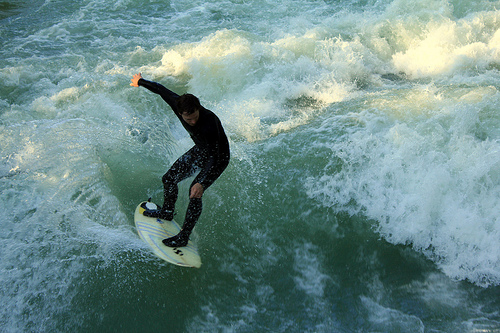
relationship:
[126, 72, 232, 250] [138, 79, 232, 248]
man has wetsuit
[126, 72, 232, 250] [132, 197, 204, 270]
man on surfboard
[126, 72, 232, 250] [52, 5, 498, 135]
man on wave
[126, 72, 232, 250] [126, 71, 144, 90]
man has a hand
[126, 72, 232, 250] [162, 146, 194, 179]
man has a thigh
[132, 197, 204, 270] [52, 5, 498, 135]
surfboard on wave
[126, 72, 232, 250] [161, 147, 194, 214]
man has leg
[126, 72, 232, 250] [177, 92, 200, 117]
man has hair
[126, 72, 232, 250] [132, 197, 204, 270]
man has surfboard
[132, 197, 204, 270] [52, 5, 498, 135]
surfboard makes wave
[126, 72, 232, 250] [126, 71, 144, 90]
man has hand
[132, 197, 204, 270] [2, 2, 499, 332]
surfboard in ocean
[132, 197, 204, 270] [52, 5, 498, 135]
surfboard in wave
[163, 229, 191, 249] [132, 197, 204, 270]
foot on surfboard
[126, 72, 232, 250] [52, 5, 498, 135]
man riding wave